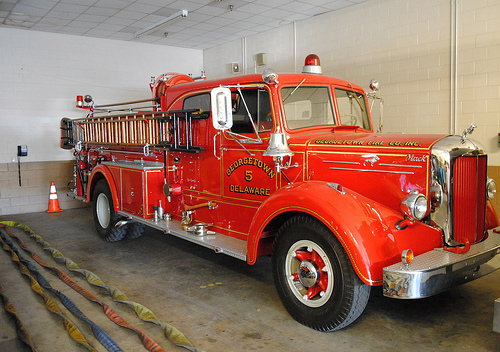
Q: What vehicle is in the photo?
A: A truck.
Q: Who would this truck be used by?
A: Firefighters.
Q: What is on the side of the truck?
A: A ladder.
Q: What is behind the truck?
A: A safety cone.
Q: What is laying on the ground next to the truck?
A: Hoses.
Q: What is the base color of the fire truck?
A: Red.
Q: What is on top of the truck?
A: A light.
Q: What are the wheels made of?
A: Rubber.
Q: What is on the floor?
A: Hose.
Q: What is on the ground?
A: Fire Truck.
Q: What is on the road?
A: Firetruck.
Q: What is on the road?
A: Firehouses.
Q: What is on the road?
A: Engine.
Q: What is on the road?
A: Truck.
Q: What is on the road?
A: Truck.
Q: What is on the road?
A: Fire hoses.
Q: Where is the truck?
A: Garage.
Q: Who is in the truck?
A: No one.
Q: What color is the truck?
A: Red.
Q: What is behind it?
A: Cone.